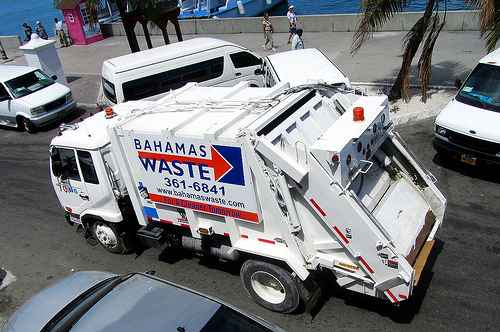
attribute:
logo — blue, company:
[132, 135, 245, 194]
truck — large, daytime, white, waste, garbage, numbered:
[48, 78, 450, 317]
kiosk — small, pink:
[58, 0, 107, 46]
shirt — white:
[286, 10, 300, 29]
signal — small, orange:
[102, 106, 117, 119]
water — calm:
[2, 1, 490, 40]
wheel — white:
[239, 255, 301, 316]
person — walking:
[263, 10, 277, 53]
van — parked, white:
[1, 64, 80, 133]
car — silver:
[1, 265, 288, 331]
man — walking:
[285, 5, 302, 44]